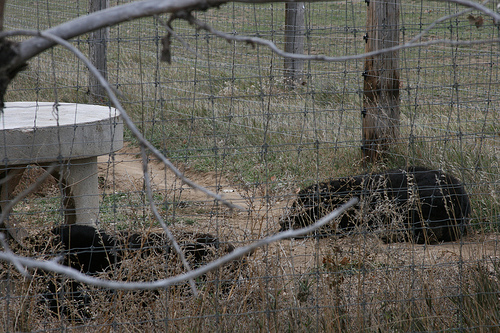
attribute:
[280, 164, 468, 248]
dog — lying down, large, laying down, dark, laying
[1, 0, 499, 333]
fence — metal, silver, wire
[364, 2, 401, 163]
post — wood, brown, wooden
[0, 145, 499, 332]
grass — turning brown, overgrown, dry, dead, growing, golden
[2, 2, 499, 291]
tree limb — bare, small, without leaves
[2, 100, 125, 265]
structure — concrete, cement, large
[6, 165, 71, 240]
space — empty